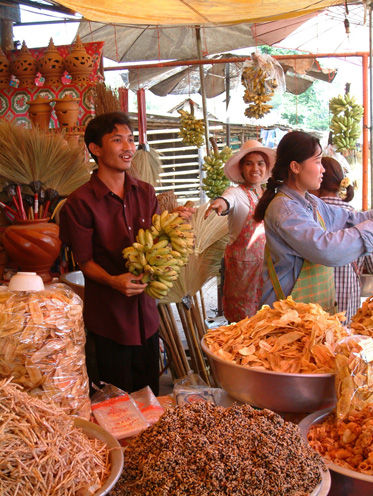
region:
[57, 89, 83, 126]
a clay pot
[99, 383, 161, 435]
a stack of plastic bags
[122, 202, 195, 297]
a bunch of bananas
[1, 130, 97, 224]
small brooms in a container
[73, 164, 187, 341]
a maroon shirt on a man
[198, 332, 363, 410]
a metal bowl on a table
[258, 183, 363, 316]
a blue shirt on a woman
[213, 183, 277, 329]
a red apron on a woman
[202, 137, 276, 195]
a hat on a woman's head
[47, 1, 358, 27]
a tarp hanging overhead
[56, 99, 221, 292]
guy holding bunch of bananas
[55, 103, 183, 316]
guy wearing brown shirt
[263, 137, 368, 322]
lady wearing blue shirt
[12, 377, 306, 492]
food piles on platters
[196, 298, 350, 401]
big bowl of food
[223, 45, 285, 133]
bananas hanging from pole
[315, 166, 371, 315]
lady in plaid shirt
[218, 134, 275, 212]
lady in white shirt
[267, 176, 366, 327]
green and yellow checked apron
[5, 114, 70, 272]
brooms in large vase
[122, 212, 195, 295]
a bunch of ripe bananas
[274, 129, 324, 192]
the head of a woman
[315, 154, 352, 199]
the head of a woman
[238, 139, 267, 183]
the head of a woman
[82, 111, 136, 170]
the head of a man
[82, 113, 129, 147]
the dark brown hair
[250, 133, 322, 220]
the dark brown hair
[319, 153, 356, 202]
the dark brown hair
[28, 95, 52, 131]
the orange earthen ware pottery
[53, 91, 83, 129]
the orange earthen ware pottery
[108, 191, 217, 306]
A bunch of bananas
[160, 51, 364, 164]
Bananas hanging from a pole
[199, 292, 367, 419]
A large steel bowl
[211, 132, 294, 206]
A woman in a white hat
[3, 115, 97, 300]
A bowl filled with straw fans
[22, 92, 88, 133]
Terra cotta pots on a shelf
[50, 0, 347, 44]
Part of a yellow canopy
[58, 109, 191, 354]
A man in a maroon shirt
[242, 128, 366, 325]
A woman in a blue shirt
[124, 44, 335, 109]
An umbrella in the background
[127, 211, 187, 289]
the bunch of bananas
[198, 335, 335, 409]
the big silver bowl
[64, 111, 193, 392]
the man holding the bunch of bananas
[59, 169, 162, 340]
the dark red buttoned up shirt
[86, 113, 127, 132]
the dark hair on the man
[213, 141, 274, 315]
the woman in an apron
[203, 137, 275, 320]
the woman in the light colored hat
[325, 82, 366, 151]
the big bunch of green bananas hanging by itself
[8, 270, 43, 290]
the white bowl turned upside down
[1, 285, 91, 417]
the big clear bag full of food